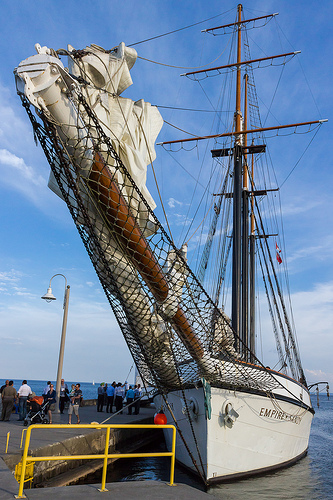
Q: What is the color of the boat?
A: White.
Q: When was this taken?
A: Daytime.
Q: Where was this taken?
A: By the dock.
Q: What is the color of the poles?
A: Yellow.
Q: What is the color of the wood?
A: Brown.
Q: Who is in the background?
A: A crowd.